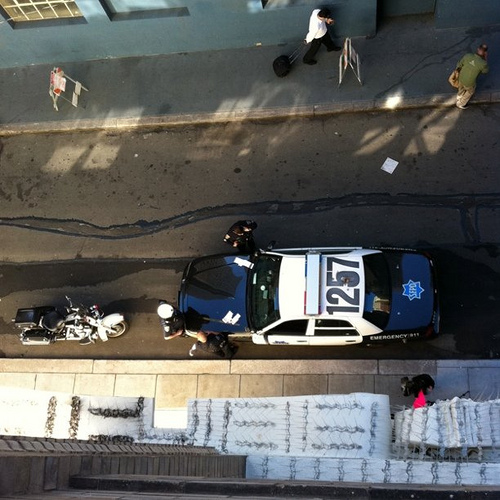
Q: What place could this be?
A: It is a street.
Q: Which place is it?
A: It is a street.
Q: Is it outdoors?
A: Yes, it is outdoors.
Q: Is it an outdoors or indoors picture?
A: It is outdoors.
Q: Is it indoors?
A: No, it is outdoors.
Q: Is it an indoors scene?
A: No, it is outdoors.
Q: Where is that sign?
A: The sign is on the side walk.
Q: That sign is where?
A: The sign is on the side walk.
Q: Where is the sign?
A: The sign is on the side walk.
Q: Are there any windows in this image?
A: Yes, there is a window.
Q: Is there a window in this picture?
A: Yes, there is a window.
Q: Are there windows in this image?
A: Yes, there is a window.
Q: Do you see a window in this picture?
A: Yes, there is a window.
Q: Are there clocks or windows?
A: Yes, there is a window.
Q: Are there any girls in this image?
A: No, there are no girls.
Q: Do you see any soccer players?
A: No, there are no soccer players.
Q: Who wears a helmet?
A: The policeman wears a helmet.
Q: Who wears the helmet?
A: The policeman wears a helmet.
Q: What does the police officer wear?
A: The police officer wears a helmet.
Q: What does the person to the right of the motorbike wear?
A: The police officer wears a helmet.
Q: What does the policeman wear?
A: The police officer wears a helmet.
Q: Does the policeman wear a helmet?
A: Yes, the policeman wears a helmet.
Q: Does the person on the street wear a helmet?
A: Yes, the policeman wears a helmet.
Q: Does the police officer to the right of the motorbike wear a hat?
A: No, the police officer wears a helmet.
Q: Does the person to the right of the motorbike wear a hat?
A: No, the police officer wears a helmet.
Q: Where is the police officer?
A: The police officer is on the street.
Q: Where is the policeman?
A: The police officer is on the street.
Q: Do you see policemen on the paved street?
A: Yes, there is a policeman on the street.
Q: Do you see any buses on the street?
A: No, there is a policeman on the street.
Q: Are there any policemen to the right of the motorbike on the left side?
A: Yes, there is a policeman to the right of the motorcycle.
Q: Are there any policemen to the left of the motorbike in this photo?
A: No, the policeman is to the right of the motorbike.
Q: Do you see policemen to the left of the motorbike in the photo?
A: No, the policeman is to the right of the motorbike.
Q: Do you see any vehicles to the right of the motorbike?
A: No, there is a policeman to the right of the motorbike.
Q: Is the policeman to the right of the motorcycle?
A: Yes, the policeman is to the right of the motorcycle.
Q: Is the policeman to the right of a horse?
A: No, the policeman is to the right of the motorcycle.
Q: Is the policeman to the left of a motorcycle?
A: No, the policeman is to the right of a motorcycle.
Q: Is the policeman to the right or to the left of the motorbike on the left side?
A: The policeman is to the right of the motorcycle.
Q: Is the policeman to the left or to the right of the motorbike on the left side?
A: The policeman is to the right of the motorcycle.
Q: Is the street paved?
A: Yes, the street is paved.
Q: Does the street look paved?
A: Yes, the street is paved.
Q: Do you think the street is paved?
A: Yes, the street is paved.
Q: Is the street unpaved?
A: No, the street is paved.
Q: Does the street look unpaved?
A: No, the street is paved.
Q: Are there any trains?
A: No, there are no trains.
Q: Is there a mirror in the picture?
A: No, there are no mirrors.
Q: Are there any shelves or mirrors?
A: No, there are no mirrors or shelves.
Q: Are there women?
A: No, there are no women.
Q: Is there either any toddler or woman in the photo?
A: No, there are no women or toddlers.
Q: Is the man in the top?
A: Yes, the man is in the top of the image.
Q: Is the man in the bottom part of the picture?
A: No, the man is in the top of the image.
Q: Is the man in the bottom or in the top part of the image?
A: The man is in the top of the image.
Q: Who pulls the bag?
A: The man pulls the bag.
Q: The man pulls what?
A: The man pulls the bag.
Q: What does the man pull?
A: The man pulls the bag.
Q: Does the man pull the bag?
A: Yes, the man pulls the bag.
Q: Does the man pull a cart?
A: No, the man pulls the bag.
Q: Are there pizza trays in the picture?
A: No, there are no pizza trays.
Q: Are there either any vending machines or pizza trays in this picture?
A: No, there are no pizza trays or vending machines.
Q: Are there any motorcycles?
A: Yes, there is a motorcycle.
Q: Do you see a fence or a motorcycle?
A: Yes, there is a motorcycle.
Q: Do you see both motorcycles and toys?
A: No, there is a motorcycle but no toys.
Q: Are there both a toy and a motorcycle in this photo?
A: No, there is a motorcycle but no toys.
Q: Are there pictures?
A: No, there are no pictures.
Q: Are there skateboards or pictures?
A: No, there are no pictures or skateboards.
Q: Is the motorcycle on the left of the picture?
A: Yes, the motorcycle is on the left of the image.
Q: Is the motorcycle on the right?
A: No, the motorcycle is on the left of the image.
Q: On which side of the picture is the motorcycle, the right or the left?
A: The motorcycle is on the left of the image.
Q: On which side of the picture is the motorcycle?
A: The motorcycle is on the left of the image.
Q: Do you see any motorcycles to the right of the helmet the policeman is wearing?
A: No, the motorcycle is to the left of the helmet.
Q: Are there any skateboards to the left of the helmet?
A: No, there is a motorcycle to the left of the helmet.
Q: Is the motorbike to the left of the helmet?
A: Yes, the motorbike is to the left of the helmet.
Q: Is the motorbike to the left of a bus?
A: No, the motorbike is to the left of the helmet.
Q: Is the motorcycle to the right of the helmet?
A: No, the motorcycle is to the left of the helmet.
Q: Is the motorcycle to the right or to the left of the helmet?
A: The motorcycle is to the left of the helmet.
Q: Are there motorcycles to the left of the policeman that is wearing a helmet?
A: Yes, there is a motorcycle to the left of the policeman.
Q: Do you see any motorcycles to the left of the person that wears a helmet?
A: Yes, there is a motorcycle to the left of the policeman.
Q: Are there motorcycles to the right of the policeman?
A: No, the motorcycle is to the left of the policeman.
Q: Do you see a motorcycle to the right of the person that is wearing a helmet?
A: No, the motorcycle is to the left of the policeman.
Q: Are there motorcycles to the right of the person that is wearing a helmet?
A: No, the motorcycle is to the left of the policeman.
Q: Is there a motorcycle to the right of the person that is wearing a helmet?
A: No, the motorcycle is to the left of the policeman.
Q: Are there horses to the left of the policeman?
A: No, there is a motorcycle to the left of the policeman.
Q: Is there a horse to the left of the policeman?
A: No, there is a motorcycle to the left of the policeman.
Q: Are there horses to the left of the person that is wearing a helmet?
A: No, there is a motorcycle to the left of the policeman.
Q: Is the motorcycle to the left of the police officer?
A: Yes, the motorcycle is to the left of the police officer.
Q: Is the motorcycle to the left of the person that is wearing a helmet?
A: Yes, the motorcycle is to the left of the police officer.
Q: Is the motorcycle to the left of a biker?
A: No, the motorcycle is to the left of the police officer.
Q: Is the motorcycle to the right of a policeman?
A: No, the motorcycle is to the left of a policeman.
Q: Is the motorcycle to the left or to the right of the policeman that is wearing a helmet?
A: The motorcycle is to the left of the police officer.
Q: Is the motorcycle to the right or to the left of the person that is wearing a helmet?
A: The motorcycle is to the left of the police officer.